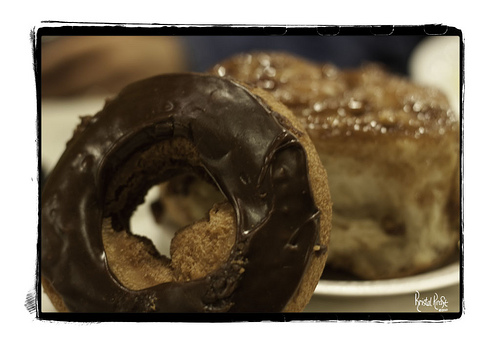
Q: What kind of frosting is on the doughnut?
A: Chocolate.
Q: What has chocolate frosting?
A: The doughnut.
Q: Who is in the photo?
A: Nobody.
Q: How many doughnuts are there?
A: One.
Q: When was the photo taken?
A: Daytime.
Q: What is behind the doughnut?
A: A cinnamon roll.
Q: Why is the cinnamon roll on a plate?
A: To serve it.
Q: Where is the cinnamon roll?
A: On a plate.